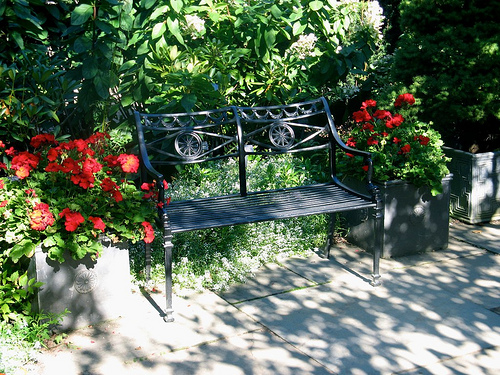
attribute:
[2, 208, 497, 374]
pavement — concrete, light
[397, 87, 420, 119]
flower — red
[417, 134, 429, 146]
flower — red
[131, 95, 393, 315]
seat — dark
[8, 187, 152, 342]
planter — grey, square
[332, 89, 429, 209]
flowers — red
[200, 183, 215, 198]
flower — white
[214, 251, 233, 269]
flower — white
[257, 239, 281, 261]
flower — white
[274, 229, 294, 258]
flower — white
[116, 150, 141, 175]
flower — red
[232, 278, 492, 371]
stone — grey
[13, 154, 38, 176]
flower — red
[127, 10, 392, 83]
flowers — white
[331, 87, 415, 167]
flowers — red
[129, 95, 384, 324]
bench — black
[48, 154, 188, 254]
flowers — red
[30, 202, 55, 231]
flower — red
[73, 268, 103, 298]
emblem — grey